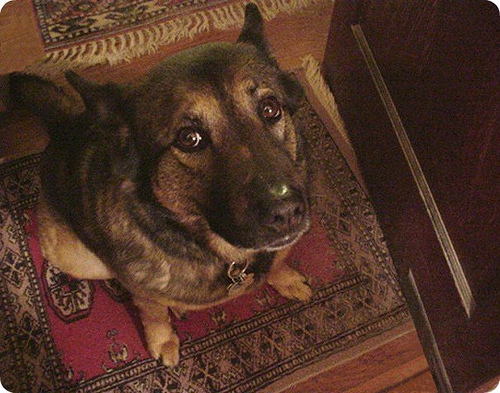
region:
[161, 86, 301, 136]
dog has big brown eyes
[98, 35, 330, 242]
brown dog looking at camera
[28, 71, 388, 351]
dog sitting on patterned rug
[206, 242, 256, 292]
dog wearing dog tags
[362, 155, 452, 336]
rug under brown door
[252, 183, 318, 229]
dog has small black nose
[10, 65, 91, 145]
dog has a long thick tail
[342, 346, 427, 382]
floor under rug is wooden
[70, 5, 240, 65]
fringe on rug behind dog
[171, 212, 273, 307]
collar on dog is black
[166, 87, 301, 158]
the dog`s eyes are brown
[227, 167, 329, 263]
the nose is black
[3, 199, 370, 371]
the rug is oriental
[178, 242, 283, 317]
the dog`s collar is metal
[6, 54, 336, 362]
the dog is sitting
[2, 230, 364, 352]
the rug is red, black and tan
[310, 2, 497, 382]
the door is open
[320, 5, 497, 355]
door is made of wood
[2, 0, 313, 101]
the floor is made of wood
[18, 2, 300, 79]
the rug has fringe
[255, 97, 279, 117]
light reflection in an eye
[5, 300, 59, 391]
boarder pattern on oriental rug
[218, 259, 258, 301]
silver dog tags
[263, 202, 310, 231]
nostrils of a dog nose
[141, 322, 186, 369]
front dog paw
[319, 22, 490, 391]
bottom of wooden door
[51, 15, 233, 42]
white fringe of oriental rug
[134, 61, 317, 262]
black and tan dog face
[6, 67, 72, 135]
bushy tail of dog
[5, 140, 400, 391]
black ,tan, and red oriental rug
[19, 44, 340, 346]
the dog looking at the camera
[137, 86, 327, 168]
the eyes of the dog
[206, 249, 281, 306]
the dog tag of the dog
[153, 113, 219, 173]
the left eye of the dog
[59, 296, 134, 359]
the carpet the dog is standing on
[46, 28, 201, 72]
the rug behind the dog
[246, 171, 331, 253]
the nose of the dog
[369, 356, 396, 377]
the hardwood floor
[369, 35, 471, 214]
the wooden object next to the dog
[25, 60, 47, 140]
the dogs tail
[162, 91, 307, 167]
brown dog eyes begging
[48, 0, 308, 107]
ears are pointed back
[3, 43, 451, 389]
dog is sitting on a red rug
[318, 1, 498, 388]
dark brown wood door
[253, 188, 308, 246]
wet brown dog nose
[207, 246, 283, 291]
dog has black collar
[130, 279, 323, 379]
tan dog paws on carpet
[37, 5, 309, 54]
rug behind the dog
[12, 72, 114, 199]
tail on dog is curled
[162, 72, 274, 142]
dog has eyebrows